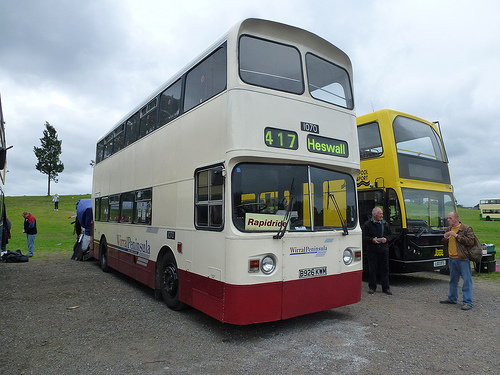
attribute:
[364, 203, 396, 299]
man — standing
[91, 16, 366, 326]
bus — two story, red, in parking lot, white, double decker, with top part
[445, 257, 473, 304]
jeans — blue, on, existing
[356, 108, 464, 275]
bus — yellow, black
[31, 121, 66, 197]
tree — tall, leafy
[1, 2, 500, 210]
clouds — grey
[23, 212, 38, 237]
jacket — red, black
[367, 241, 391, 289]
pants — dark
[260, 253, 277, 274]
light — off, yellow, existing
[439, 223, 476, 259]
jacket — brown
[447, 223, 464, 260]
shirt — yellow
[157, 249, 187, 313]
wheel — existing